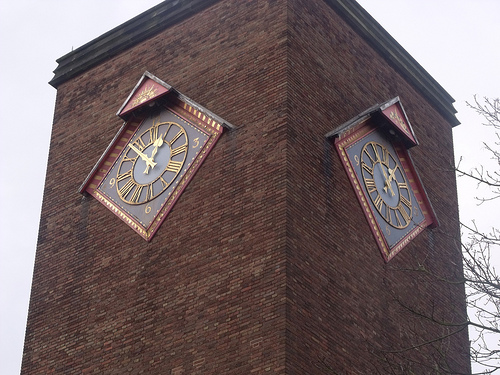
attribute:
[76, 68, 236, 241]
clock — diamond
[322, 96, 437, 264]
clock — diamond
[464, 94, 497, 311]
tree — leafless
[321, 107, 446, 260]
clock — black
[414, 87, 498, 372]
branches — leafless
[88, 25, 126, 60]
border — black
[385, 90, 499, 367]
tree — leafless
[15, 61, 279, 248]
clock — diamond shaped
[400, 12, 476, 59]
sky — gray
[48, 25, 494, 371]
wall — brick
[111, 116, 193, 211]
clock — black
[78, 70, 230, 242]
edge — gold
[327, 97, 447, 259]
edge — gold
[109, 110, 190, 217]
face — black and gold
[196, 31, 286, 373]
bricks — rectangular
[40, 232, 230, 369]
bricks — rectangular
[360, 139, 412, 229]
numbers — gold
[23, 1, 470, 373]
building — red, fancy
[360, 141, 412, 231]
clock — face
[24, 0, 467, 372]
tower — thin, aging 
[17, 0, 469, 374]
clock tower — large, brick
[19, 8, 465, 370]
structure — strong 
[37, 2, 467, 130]
roof — black